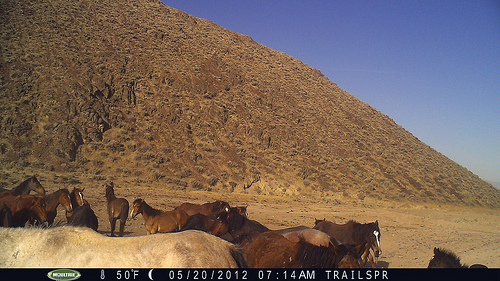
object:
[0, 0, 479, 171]
hill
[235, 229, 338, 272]
horse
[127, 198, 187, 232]
horse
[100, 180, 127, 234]
horse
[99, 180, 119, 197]
head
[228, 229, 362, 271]
horse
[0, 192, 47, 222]
horse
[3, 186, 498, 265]
desert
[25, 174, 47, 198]
head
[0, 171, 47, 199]
horse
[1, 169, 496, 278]
group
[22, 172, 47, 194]
head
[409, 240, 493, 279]
horse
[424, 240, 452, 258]
ear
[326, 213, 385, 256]
horse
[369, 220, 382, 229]
ears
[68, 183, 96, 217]
horse head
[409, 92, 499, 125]
white clouds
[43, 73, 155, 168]
outcrop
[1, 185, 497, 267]
ground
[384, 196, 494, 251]
dessert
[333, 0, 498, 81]
blue sky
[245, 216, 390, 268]
horse's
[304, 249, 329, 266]
black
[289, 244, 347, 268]
mane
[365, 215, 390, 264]
head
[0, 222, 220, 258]
back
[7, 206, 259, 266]
horse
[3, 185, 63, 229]
horse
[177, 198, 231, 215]
horse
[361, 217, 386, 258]
horse_head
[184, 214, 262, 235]
horse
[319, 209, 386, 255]
horse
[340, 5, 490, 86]
sky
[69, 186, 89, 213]
head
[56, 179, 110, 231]
horse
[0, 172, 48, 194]
brown horse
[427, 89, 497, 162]
clouds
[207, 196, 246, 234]
head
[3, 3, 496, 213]
hillside